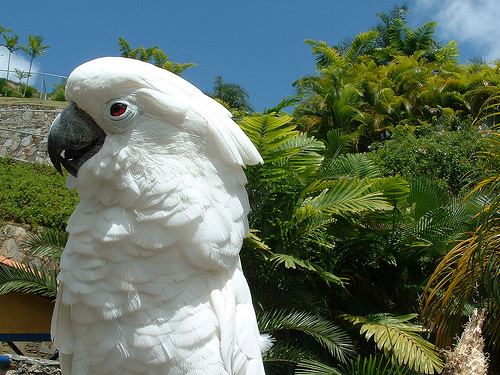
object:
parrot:
[45, 55, 264, 375]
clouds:
[441, 0, 475, 16]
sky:
[0, 3, 499, 112]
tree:
[371, 0, 444, 62]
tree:
[302, 29, 379, 67]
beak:
[47, 102, 106, 178]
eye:
[108, 101, 129, 118]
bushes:
[452, 127, 499, 194]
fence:
[0, 65, 68, 100]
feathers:
[132, 225, 183, 250]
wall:
[7, 107, 48, 164]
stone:
[9, 137, 19, 150]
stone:
[21, 135, 35, 147]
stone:
[26, 147, 38, 156]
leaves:
[357, 192, 384, 200]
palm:
[240, 109, 398, 298]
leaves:
[432, 236, 477, 274]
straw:
[437, 308, 488, 375]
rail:
[0, 68, 67, 80]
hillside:
[0, 92, 67, 286]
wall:
[2, 224, 56, 276]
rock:
[4, 240, 22, 261]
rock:
[2, 225, 27, 242]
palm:
[0, 35, 20, 96]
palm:
[18, 30, 51, 98]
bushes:
[372, 135, 449, 181]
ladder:
[2, 349, 59, 374]